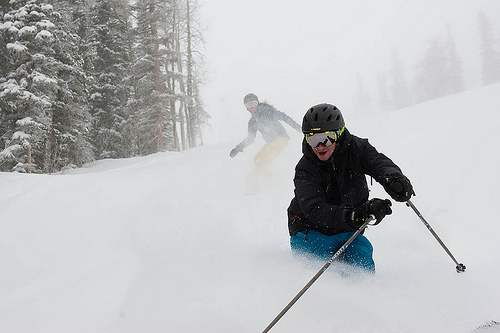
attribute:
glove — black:
[359, 196, 391, 228]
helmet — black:
[285, 96, 341, 143]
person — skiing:
[212, 84, 436, 285]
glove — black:
[380, 172, 413, 202]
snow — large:
[1, 87, 496, 331]